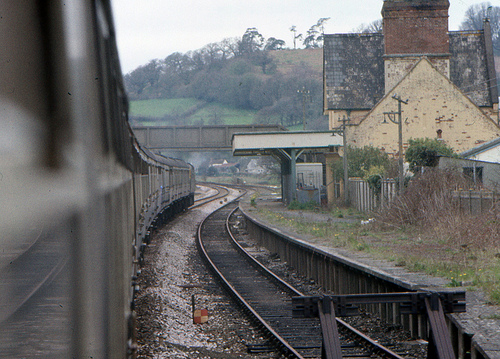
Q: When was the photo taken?
A: Daytime.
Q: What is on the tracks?
A: Train.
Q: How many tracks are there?
A: Two.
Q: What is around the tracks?
A: Gravel.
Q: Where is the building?
A: Beside the tracks.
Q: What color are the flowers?
A: Yellow.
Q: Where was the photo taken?
A: Empty train depot.